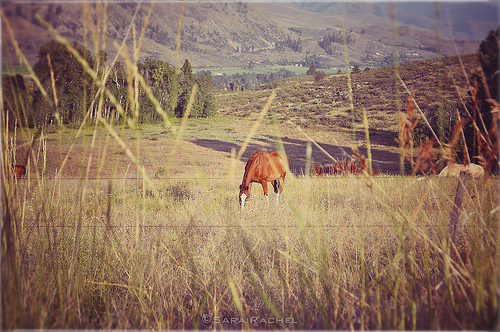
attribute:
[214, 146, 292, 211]
horse — eating, standing, field, brown, white, alone, grazing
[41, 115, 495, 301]
field — large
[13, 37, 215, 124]
trees — tall, green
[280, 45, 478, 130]
hill — bare, present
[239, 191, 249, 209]
stripe — white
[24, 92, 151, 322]
weeds — tall, present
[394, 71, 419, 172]
tree — tall, leafy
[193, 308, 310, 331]
words — present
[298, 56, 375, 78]
trees — green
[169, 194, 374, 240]
grass — green, overgrown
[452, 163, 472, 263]
post — wooden, brown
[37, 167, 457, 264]
fence — wire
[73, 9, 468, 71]
mountains — present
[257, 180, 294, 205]
legs — brown, white